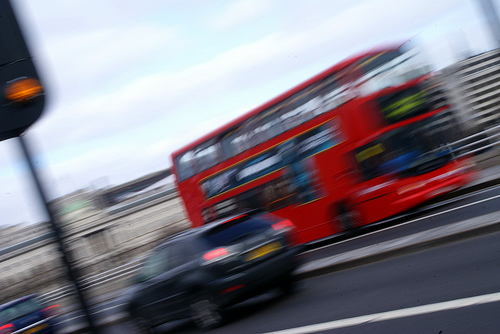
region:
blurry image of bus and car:
[21, 15, 425, 327]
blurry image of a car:
[27, 192, 332, 322]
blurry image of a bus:
[204, 73, 454, 248]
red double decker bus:
[73, 60, 496, 218]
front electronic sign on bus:
[373, 83, 435, 126]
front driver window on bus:
[406, 110, 478, 171]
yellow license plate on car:
[222, 212, 315, 265]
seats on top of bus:
[185, 77, 332, 172]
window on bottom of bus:
[224, 170, 330, 222]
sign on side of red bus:
[320, 135, 399, 162]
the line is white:
[347, 313, 358, 328]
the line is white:
[330, 314, 345, 332]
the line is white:
[338, 318, 351, 329]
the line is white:
[347, 308, 354, 333]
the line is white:
[362, 319, 366, 330]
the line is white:
[356, 306, 368, 330]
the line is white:
[356, 318, 367, 331]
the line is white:
[342, 305, 353, 332]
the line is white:
[355, 311, 364, 330]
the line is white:
[371, 305, 378, 330]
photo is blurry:
[10, 1, 498, 326]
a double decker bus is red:
[150, 30, 496, 272]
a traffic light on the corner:
[3, 6, 58, 158]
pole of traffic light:
[18, 135, 101, 331]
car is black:
[93, 202, 316, 328]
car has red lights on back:
[183, 203, 292, 266]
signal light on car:
[216, 205, 253, 235]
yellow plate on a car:
[241, 235, 281, 265]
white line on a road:
[310, 271, 495, 329]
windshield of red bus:
[365, 120, 459, 177]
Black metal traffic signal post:
[18, 133, 80, 324]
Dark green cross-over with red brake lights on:
[121, 207, 304, 327]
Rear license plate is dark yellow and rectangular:
[238, 237, 290, 264]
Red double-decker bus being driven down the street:
[187, 83, 446, 239]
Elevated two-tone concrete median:
[325, 207, 499, 263]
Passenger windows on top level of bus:
[174, 76, 380, 167]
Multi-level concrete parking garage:
[431, 57, 498, 144]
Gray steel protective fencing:
[450, 127, 499, 157]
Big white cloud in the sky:
[84, 77, 246, 103]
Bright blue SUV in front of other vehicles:
[1, 288, 65, 332]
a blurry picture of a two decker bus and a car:
[73, 22, 498, 330]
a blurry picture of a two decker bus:
[293, 57, 473, 209]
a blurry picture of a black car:
[115, 219, 292, 319]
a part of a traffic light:
[1, 10, 53, 141]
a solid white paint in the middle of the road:
[328, 296, 447, 331]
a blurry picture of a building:
[461, 9, 494, 89]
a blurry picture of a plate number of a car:
[246, 240, 293, 261]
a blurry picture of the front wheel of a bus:
[326, 191, 371, 238]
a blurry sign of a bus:
[382, 89, 432, 117]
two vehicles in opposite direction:
[118, 52, 476, 329]